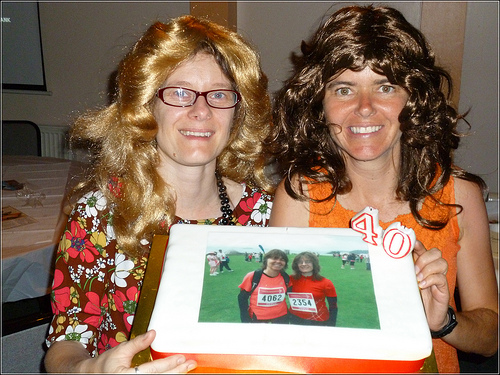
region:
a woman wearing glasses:
[95, 37, 291, 212]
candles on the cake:
[345, 205, 415, 260]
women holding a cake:
[57, 23, 455, 368]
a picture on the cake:
[195, 235, 365, 305]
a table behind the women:
[1, 146, 81, 256]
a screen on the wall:
[1, 15, 46, 85]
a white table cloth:
[6, 160, 46, 277]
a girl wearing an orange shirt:
[280, 20, 465, 260]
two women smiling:
[48, 40, 479, 362]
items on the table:
[7, 173, 52, 240]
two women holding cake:
[43, 12, 498, 374]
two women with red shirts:
[234, 248, 341, 325]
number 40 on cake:
[347, 202, 417, 264]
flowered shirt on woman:
[40, 179, 270, 357]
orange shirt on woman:
[299, 164, 467, 368]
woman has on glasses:
[42, 26, 276, 364]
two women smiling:
[116, 5, 455, 195]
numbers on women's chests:
[249, 275, 324, 325]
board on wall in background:
[0, 2, 50, 98]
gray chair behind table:
[0, 116, 53, 166]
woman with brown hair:
[355, 20, 375, 45]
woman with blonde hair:
[121, 94, 134, 120]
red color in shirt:
[77, 245, 90, 261]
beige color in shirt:
[91, 235, 101, 240]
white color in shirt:
[118, 261, 123, 271]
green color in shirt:
[83, 277, 95, 289]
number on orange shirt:
[259, 295, 284, 306]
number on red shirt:
[291, 295, 315, 309]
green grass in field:
[351, 287, 363, 315]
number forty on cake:
[348, 206, 414, 260]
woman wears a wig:
[57, 3, 295, 287]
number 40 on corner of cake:
[126, 198, 440, 374]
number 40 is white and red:
[341, 202, 418, 265]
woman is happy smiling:
[271, 5, 484, 220]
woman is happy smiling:
[71, 9, 301, 248]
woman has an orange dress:
[250, 2, 495, 374]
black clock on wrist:
[431, 303, 462, 343]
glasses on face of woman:
[146, 77, 245, 117]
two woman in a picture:
[193, 231, 388, 337]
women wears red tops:
[232, 241, 347, 331]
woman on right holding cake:
[258, 5, 493, 373]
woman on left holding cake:
[41, 10, 289, 374]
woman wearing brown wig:
[265, 3, 490, 235]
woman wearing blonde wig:
[65, 8, 289, 250]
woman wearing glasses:
[154, 73, 246, 123]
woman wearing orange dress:
[278, 159, 483, 374]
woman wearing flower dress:
[38, 162, 290, 374]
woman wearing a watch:
[424, 299, 461, 338]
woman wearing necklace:
[201, 168, 238, 239]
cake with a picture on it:
[113, 204, 433, 373]